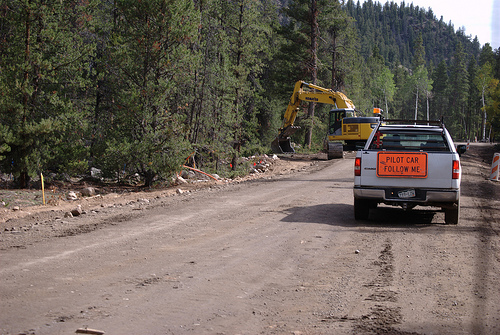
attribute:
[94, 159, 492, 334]
road — leveled, dirt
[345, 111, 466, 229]
truck — white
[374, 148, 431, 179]
sign — orange, black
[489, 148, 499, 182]
barrel — orange, white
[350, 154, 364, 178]
tail — red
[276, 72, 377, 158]
machinery — large, orange, yellow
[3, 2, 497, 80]
hillside — green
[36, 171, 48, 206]
pole — yellow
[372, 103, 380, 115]
light — yellow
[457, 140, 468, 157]
mirror — black